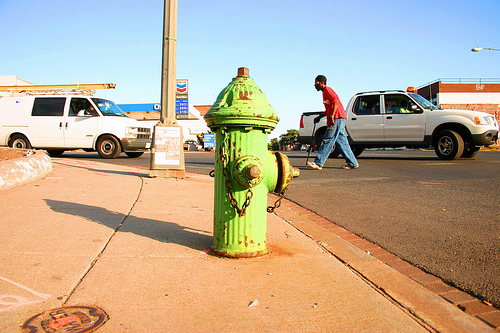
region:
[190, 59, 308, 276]
fire hydrant on a sidewalk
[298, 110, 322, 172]
cane in a persons hand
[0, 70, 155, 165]
vehicle on a street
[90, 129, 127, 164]
front wheel on a vehicle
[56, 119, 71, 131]
door handles on a vehicle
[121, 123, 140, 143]
front headlight on a vehicle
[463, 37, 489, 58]
street light on a pole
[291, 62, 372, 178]
person with a red shirt walking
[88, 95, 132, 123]
front windshield of a vehicle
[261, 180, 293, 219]
chain on a fire hydrant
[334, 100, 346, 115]
part of a red top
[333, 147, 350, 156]
part of a jeans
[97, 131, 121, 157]
front wheel of a vehicle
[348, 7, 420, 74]
part of the sky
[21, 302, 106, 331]
lid of a sewage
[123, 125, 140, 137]
headlight of a vehicle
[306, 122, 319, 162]
part of a walking stick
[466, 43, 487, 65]
part of a sreetlight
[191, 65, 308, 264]
A green fire hydrant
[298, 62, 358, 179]
A man walking across street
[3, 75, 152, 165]
A white work van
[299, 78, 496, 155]
A white pickup truck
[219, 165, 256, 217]
A chain on a fire hydrant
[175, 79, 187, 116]
A Gas station price sign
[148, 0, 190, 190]
A pole on a sidewalk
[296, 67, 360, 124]
A man wearing a red shirt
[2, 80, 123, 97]
A ladder on a van roof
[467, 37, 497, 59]
A street light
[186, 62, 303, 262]
Fire hydrant shows sign of rusting.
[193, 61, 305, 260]
Fire hydrant is bright green.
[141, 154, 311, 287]
Fire hydrant is near edge of sidewalk.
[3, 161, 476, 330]
The sidewalk is cemented.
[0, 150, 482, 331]
Cemented sidewalk is dry.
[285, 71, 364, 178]
Man is crossing the street.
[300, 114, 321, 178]
Man is using a cane.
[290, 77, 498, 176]
White truck is driving around man.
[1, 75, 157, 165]
White van is waiting at intersection.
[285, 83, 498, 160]
The pickup truck has four doors.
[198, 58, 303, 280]
rusty green fire hydrant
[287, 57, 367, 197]
man walking across the street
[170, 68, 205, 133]
Chevron gas station sign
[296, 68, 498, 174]
white pick-up truck turning corner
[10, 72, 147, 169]
white utility van at corner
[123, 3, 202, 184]
street lamp pole on corner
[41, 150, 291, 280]
shadow of fire hydrant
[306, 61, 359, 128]
man wearing red shirt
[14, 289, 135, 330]
utility cover in sidewalk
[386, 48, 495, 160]
brown building on street corner